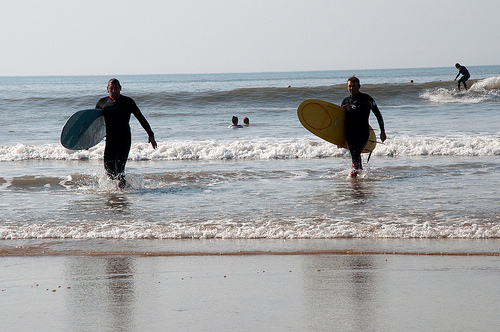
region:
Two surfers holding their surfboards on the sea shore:
[51, 62, 401, 204]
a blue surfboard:
[58, 104, 114, 154]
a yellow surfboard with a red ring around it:
[293, 100, 380, 150]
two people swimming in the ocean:
[227, 107, 253, 128]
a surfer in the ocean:
[434, 58, 484, 98]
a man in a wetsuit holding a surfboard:
[299, 72, 386, 179]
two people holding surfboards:
[58, 69, 389, 191]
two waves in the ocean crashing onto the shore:
[0, 134, 498, 247]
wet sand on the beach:
[3, 245, 496, 328]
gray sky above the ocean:
[0, 2, 485, 74]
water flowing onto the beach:
[2, 223, 495, 258]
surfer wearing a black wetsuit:
[61, 78, 157, 192]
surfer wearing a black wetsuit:
[296, 77, 386, 179]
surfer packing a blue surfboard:
[59, 78, 157, 189]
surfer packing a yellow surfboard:
[295, 75, 385, 179]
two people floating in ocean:
[227, 113, 249, 129]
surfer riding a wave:
[450, 60, 470, 93]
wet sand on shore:
[3, 257, 499, 329]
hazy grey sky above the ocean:
[0, 1, 498, 77]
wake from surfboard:
[419, 75, 497, 104]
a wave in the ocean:
[0, 77, 498, 110]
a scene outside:
[0, 0, 497, 322]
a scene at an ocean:
[2, 0, 499, 330]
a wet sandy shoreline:
[2, 232, 496, 330]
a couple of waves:
[5, 135, 499, 260]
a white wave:
[4, 135, 499, 166]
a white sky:
[0, 0, 496, 90]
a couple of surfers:
[52, 69, 399, 203]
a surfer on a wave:
[427, 50, 494, 110]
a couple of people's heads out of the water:
[219, 104, 258, 141]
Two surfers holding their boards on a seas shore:
[47, 72, 399, 216]